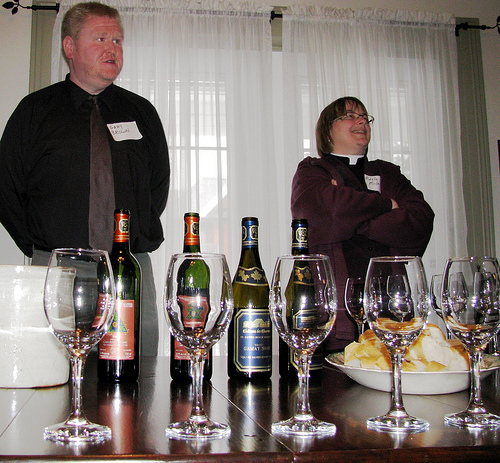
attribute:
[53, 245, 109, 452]
glass — wine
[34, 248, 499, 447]
glasses — five, empty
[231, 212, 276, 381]
bottle — green, wine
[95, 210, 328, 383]
bottles — wine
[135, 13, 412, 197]
curtains — white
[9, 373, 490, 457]
table — wooden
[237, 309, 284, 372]
sticker — blue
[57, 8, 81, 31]
hair — short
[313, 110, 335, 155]
hair — short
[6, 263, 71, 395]
canister — white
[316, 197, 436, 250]
arms — crossed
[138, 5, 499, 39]
rod — long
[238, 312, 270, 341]
label — blue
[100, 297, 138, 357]
label — red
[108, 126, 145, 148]
name tag — white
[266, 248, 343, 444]
glass — middle